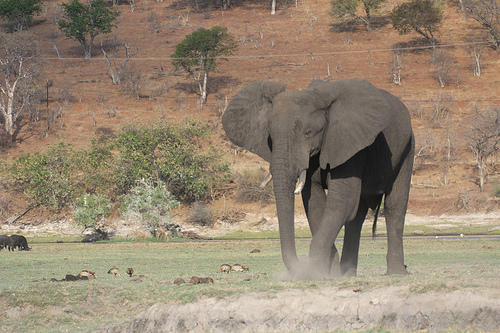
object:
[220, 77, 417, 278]
elephant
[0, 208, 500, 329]
prairie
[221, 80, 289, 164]
ears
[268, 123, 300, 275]
trunk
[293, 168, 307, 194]
elephant tusk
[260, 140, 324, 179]
mouth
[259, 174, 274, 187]
tusk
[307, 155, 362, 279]
legs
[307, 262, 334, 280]
foot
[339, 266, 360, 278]
foot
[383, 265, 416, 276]
foot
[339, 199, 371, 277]
leg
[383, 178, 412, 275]
leg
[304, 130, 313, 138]
eye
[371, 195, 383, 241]
tail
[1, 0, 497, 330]
field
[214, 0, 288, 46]
grass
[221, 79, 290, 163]
ear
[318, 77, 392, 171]
ear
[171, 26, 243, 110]
trees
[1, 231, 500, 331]
dirt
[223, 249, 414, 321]
dust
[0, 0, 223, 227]
hill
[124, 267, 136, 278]
animals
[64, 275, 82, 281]
animals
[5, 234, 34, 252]
animals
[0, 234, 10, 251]
animals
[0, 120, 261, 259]
tree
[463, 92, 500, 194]
trees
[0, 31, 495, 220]
dirt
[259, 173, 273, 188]
tusks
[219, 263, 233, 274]
animals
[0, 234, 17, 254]
rhinos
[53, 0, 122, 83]
trees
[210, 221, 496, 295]
grass